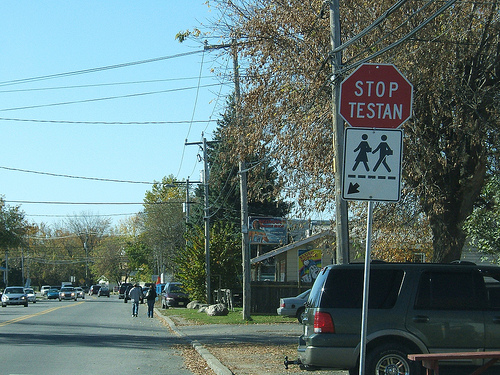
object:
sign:
[339, 55, 413, 131]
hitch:
[281, 352, 306, 370]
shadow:
[1, 317, 297, 354]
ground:
[0, 291, 295, 373]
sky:
[0, 0, 274, 231]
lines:
[0, 291, 86, 329]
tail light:
[311, 307, 338, 341]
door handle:
[409, 316, 432, 326]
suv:
[289, 260, 499, 372]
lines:
[0, 166, 202, 206]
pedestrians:
[351, 133, 393, 176]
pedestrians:
[127, 283, 145, 318]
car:
[284, 258, 499, 373]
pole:
[202, 137, 212, 305]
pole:
[184, 178, 190, 304]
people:
[142, 284, 158, 318]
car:
[58, 287, 78, 302]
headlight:
[71, 293, 74, 296]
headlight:
[60, 293, 65, 296]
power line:
[0, 195, 190, 205]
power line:
[0, 161, 183, 189]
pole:
[358, 198, 378, 373]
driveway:
[170, 320, 321, 340]